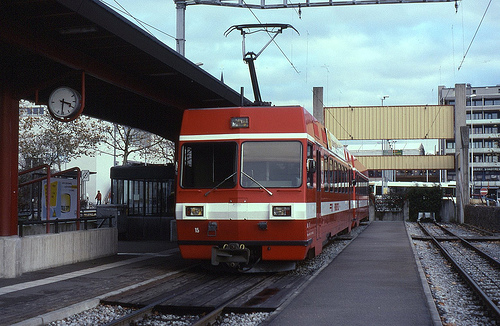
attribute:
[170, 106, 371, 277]
train — red, white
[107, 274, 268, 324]
track — train track, empty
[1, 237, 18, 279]
block — concrete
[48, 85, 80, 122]
clock — white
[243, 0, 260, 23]
wire — electric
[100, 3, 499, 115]
sky — cloudy, blue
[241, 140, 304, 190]
windshield — clear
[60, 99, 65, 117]
hand — black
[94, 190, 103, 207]
person — standing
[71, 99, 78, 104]
dial — black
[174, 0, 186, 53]
pole — metal